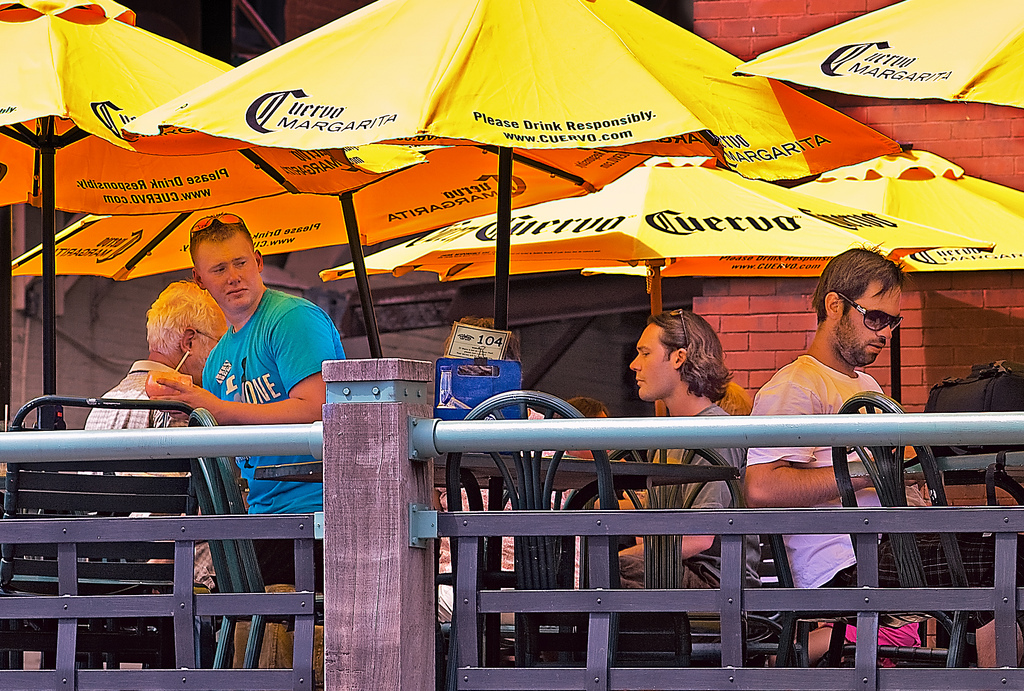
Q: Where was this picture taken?
A: Sidewalk cafe.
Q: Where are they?
A: Sitting outside.